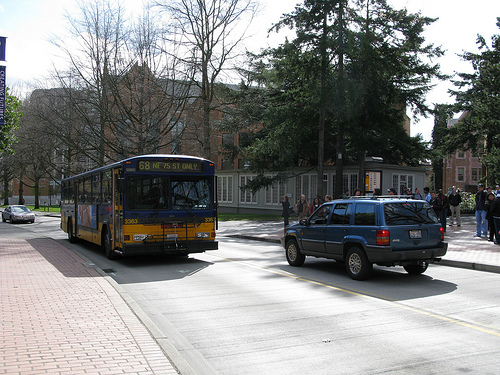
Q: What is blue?
A: Jeep.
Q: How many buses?
A: One.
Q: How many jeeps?
A: One.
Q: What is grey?
A: Road.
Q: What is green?
A: Trees.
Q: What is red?
A: Taillights.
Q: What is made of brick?
A: Sidewalk.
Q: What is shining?
A: Sun.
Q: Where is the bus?
A: Left.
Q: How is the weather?
A: Fair.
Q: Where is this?
A: Street scene.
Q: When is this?
A: Afternoon.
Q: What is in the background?
A: Buildings.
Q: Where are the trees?
A: Next to street.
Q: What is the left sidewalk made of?
A: Bricks.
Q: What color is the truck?
A: Blue.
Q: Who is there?
A: No one.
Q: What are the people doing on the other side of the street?
A: Standing.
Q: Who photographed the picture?
A: Pedestrian.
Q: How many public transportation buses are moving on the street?
A: 1.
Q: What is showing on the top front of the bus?
A: Street name.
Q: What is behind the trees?
A: Buildings.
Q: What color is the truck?
A: Blue.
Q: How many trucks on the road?
A: One.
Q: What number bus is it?
A: 68.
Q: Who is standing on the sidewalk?
A: Group of people.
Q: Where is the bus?
A: Left side.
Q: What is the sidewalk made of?
A: Bricks.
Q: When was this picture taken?
A: Midday.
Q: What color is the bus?
A: Blue and yellow.